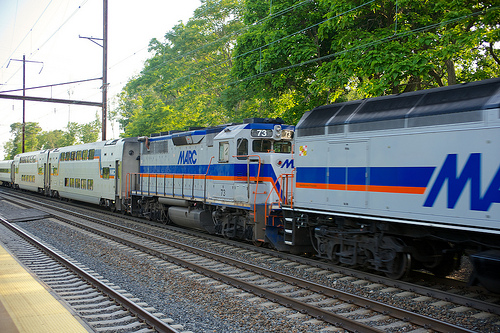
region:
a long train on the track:
[6, 79, 498, 314]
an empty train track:
[3, 188, 407, 331]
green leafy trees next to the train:
[108, 3, 496, 124]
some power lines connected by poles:
[3, 3, 111, 135]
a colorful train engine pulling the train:
[136, 124, 278, 208]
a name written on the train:
[172, 147, 197, 166]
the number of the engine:
[246, 121, 271, 138]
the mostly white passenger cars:
[1, 142, 128, 207]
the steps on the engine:
[268, 195, 290, 245]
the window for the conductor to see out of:
[252, 139, 293, 154]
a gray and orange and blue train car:
[292, 108, 498, 282]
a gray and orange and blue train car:
[137, 120, 291, 242]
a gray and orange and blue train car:
[50, 136, 138, 208]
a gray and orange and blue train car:
[14, 146, 53, 188]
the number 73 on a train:
[255, 128, 269, 137]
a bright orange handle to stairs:
[263, 174, 286, 221]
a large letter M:
[425, 148, 482, 210]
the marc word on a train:
[176, 144, 197, 167]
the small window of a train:
[236, 135, 251, 163]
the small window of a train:
[252, 139, 269, 152]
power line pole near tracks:
[93, 0, 111, 135]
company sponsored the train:
[175, 147, 195, 164]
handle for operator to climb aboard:
[250, 151, 260, 221]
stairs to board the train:
[250, 181, 285, 241]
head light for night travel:
[270, 120, 280, 140]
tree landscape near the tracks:
[155, 0, 377, 115]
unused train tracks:
[67, 245, 312, 300]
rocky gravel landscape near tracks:
[65, 230, 200, 325]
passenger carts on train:
[7, 132, 132, 207]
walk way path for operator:
[5, 205, 41, 220]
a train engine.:
[110, 112, 299, 255]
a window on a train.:
[233, 132, 251, 170]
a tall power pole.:
[72, 0, 122, 148]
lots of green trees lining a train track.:
[115, 0, 498, 142]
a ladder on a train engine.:
[250, 165, 304, 269]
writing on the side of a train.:
[418, 133, 495, 209]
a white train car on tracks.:
[52, 127, 142, 222]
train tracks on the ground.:
[0, 183, 499, 330]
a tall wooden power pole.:
[0, 5, 112, 160]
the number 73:
[249, 120, 274, 138]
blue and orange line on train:
[326, 153, 423, 224]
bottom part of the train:
[321, 226, 402, 271]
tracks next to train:
[200, 234, 290, 318]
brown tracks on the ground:
[170, 233, 272, 313]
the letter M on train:
[415, 138, 496, 207]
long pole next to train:
[58, 50, 129, 146]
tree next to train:
[231, 7, 347, 83]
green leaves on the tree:
[252, 3, 369, 85]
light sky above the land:
[31, 15, 85, 71]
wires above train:
[214, 15, 291, 97]